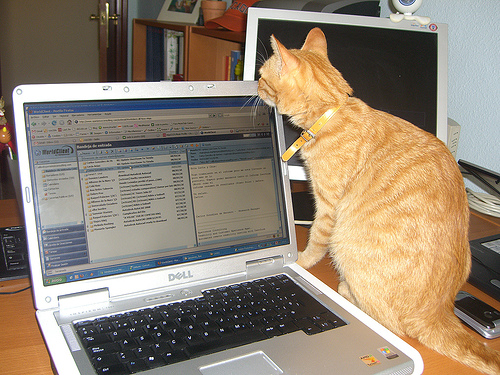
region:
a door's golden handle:
[83, 2, 123, 52]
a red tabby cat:
[253, 33, 498, 354]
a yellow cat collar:
[276, 97, 388, 154]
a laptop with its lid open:
[13, 80, 347, 367]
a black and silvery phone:
[457, 285, 499, 345]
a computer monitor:
[341, 10, 467, 126]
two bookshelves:
[132, 16, 238, 81]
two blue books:
[143, 27, 163, 82]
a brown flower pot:
[196, 0, 231, 27]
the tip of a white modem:
[447, 119, 464, 154]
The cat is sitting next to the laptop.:
[230, 73, 466, 353]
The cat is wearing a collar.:
[286, 110, 366, 155]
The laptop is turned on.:
[53, 112, 301, 277]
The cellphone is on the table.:
[442, 284, 497, 350]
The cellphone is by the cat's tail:
[397, 283, 497, 350]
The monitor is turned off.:
[261, 9, 453, 204]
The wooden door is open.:
[78, 6, 129, 86]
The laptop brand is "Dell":
[146, 260, 218, 297]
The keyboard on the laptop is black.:
[111, 303, 324, 344]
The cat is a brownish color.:
[285, 60, 443, 277]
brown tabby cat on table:
[281, 50, 471, 320]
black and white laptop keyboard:
[101, 312, 344, 349]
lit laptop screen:
[34, 105, 269, 253]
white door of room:
[20, 10, 90, 73]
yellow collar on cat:
[296, 97, 352, 154]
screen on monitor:
[350, 17, 440, 106]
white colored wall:
[456, 10, 498, 140]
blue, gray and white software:
[33, 105, 275, 242]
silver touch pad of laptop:
[206, 360, 286, 372]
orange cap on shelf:
[213, 6, 242, 32]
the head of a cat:
[251, 22, 346, 126]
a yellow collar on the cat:
[281, 88, 353, 162]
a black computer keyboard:
[73, 270, 350, 373]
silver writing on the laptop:
[163, 266, 195, 283]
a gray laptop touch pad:
[196, 343, 296, 373]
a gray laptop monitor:
[10, 77, 302, 313]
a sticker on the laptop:
[376, 340, 402, 361]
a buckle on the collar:
[298, 123, 318, 144]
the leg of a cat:
[289, 185, 339, 269]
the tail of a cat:
[419, 309, 499, 374]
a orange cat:
[255, 43, 483, 366]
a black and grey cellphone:
[442, 283, 498, 342]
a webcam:
[382, 0, 431, 22]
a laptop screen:
[17, 86, 285, 278]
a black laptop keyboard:
[65, 266, 346, 373]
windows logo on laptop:
[374, 339, 402, 364]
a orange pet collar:
[270, 102, 348, 166]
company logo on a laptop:
[158, 266, 203, 293]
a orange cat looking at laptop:
[192, 33, 487, 373]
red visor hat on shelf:
[200, 5, 251, 35]